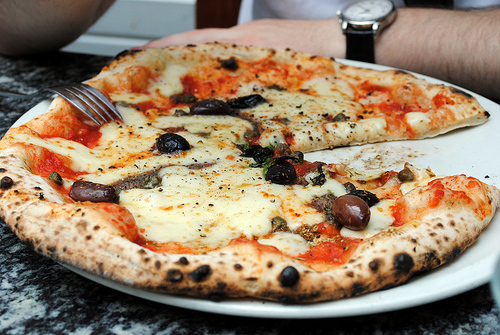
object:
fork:
[1, 78, 123, 125]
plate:
[1, 57, 500, 321]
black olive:
[156, 131, 189, 152]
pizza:
[2, 41, 499, 303]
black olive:
[264, 157, 297, 186]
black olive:
[332, 194, 371, 230]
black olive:
[69, 178, 114, 204]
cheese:
[21, 60, 438, 255]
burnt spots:
[188, 263, 213, 282]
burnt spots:
[13, 214, 26, 221]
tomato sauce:
[13, 141, 94, 182]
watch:
[334, 0, 398, 65]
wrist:
[303, 16, 346, 60]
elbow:
[0, 0, 115, 57]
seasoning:
[99, 87, 388, 249]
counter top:
[1, 48, 498, 334]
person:
[0, 0, 500, 105]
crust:
[1, 41, 499, 305]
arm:
[334, 6, 500, 106]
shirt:
[233, 1, 499, 33]